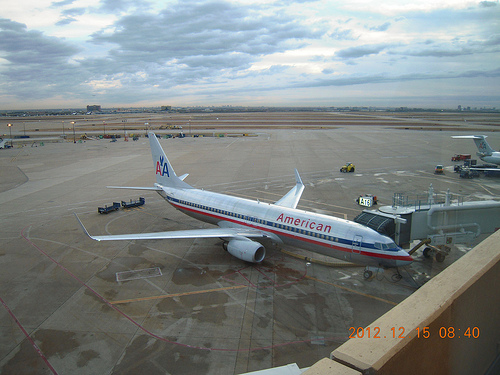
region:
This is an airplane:
[65, 111, 440, 322]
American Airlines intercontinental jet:
[78, 127, 410, 264]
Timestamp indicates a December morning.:
[347, 325, 481, 340]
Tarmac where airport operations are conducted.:
[0, 134, 498, 374]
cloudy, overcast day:
[1, 0, 497, 110]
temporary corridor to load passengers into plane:
[353, 203, 413, 249]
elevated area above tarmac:
[301, 223, 499, 373]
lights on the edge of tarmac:
[69, 120, 78, 142]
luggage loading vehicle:
[98, 198, 145, 212]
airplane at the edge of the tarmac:
[453, 133, 498, 171]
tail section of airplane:
[103, 133, 195, 191]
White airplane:
[75, 132, 417, 276]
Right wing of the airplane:
[75, 215, 283, 245]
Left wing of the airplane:
[271, 165, 308, 208]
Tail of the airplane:
[105, 128, 190, 193]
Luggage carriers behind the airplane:
[95, 197, 147, 214]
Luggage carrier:
[93, 198, 121, 215]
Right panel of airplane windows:
[160, 191, 340, 244]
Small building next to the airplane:
[354, 193, 496, 285]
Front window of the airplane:
[371, 240, 398, 251]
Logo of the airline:
[152, 152, 172, 180]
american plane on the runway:
[65, 112, 427, 304]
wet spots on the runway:
[146, 287, 231, 334]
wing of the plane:
[71, 213, 146, 259]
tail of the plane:
[140, 125, 172, 185]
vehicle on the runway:
[333, 150, 358, 180]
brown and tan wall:
[391, 292, 482, 318]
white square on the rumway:
[105, 261, 162, 283]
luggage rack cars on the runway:
[81, 190, 156, 216]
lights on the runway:
[50, 115, 85, 140]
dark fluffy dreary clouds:
[136, 23, 249, 81]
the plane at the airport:
[48, 98, 472, 373]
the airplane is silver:
[84, 114, 396, 311]